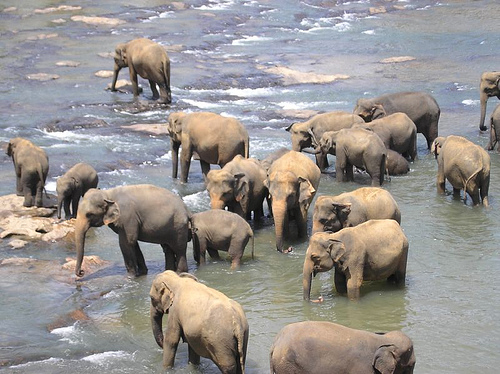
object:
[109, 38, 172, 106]
elephant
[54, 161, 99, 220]
elephant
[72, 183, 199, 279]
elephant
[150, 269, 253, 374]
elephant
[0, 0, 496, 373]
water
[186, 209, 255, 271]
elephant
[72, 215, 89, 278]
trunk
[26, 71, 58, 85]
rocks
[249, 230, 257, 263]
tail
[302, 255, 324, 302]
trunk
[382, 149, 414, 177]
elephant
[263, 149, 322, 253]
elephant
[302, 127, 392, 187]
elephant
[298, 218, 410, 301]
elephant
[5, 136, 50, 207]
elephants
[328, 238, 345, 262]
ear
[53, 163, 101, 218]
elephants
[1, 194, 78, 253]
rock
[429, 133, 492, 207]
elephant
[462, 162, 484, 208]
tail